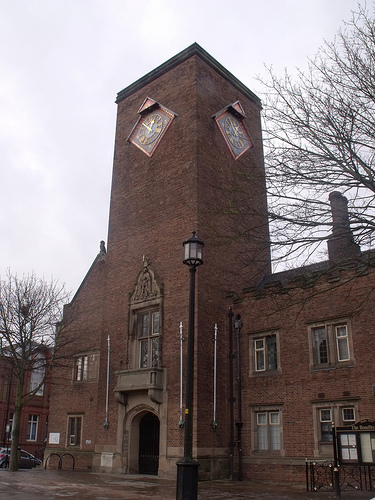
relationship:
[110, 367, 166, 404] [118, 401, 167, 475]
balcony over entryway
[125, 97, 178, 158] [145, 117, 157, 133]
clock has hand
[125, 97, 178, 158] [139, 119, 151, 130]
clock has hand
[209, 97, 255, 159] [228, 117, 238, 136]
clock has hand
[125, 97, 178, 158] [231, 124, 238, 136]
clock has hand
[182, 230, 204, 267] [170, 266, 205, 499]
light on pole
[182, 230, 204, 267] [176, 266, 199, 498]
light on pole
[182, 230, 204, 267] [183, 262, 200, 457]
light on pole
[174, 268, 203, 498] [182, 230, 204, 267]
pole on light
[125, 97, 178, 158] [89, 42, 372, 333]
clock on building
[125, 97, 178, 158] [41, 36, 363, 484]
clock on building